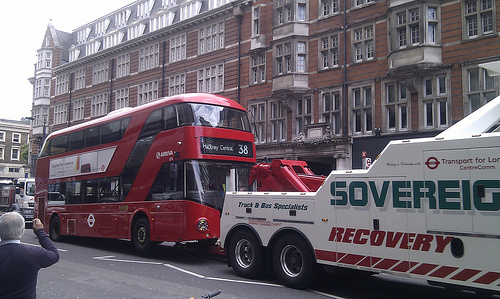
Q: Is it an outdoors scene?
A: Yes, it is outdoors.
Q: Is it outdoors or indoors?
A: It is outdoors.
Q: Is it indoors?
A: No, it is outdoors.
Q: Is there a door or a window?
A: Yes, there is a window.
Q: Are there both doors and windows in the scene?
A: No, there is a window but no doors.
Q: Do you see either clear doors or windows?
A: Yes, there is a clear window.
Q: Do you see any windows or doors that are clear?
A: Yes, the window is clear.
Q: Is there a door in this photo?
A: No, there are no doors.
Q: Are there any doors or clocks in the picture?
A: No, there are no doors or clocks.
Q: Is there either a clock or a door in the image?
A: No, there are no doors or clocks.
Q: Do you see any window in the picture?
A: Yes, there is a window.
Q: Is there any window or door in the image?
A: Yes, there is a window.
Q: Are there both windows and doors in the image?
A: No, there is a window but no doors.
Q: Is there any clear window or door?
A: Yes, there is a clear window.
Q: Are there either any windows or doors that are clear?
A: Yes, the window is clear.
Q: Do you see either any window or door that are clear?
A: Yes, the window is clear.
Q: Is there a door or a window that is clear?
A: Yes, the window is clear.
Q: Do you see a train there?
A: No, there are no trains.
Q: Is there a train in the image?
A: No, there are no trains.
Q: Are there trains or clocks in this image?
A: No, there are no trains or clocks.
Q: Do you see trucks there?
A: Yes, there is a truck.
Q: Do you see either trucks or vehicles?
A: Yes, there is a truck.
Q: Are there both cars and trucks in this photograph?
A: No, there is a truck but no cars.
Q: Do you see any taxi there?
A: No, there are no taxis.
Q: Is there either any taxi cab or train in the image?
A: No, there are no taxis or trains.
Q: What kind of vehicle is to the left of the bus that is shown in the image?
A: The vehicle is a truck.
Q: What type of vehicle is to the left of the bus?
A: The vehicle is a truck.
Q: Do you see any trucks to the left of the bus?
A: Yes, there is a truck to the left of the bus.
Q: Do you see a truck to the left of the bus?
A: Yes, there is a truck to the left of the bus.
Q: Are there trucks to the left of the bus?
A: Yes, there is a truck to the left of the bus.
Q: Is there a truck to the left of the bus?
A: Yes, there is a truck to the left of the bus.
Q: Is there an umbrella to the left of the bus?
A: No, there is a truck to the left of the bus.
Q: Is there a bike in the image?
A: No, there are no bikes.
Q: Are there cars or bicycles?
A: No, there are no bicycles or cars.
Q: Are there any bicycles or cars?
A: No, there are no bicycles or cars.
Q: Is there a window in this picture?
A: Yes, there are windows.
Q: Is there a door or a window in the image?
A: Yes, there are windows.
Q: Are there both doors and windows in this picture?
A: No, there are windows but no doors.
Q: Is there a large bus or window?
A: Yes, there are large windows.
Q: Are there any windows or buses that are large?
A: Yes, the windows are large.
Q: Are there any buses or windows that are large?
A: Yes, the windows are large.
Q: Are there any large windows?
A: Yes, there are large windows.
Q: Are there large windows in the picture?
A: Yes, there are large windows.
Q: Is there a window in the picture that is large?
A: Yes, there are windows that are large.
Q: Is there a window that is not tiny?
A: Yes, there are large windows.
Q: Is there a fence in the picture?
A: No, there are no fences.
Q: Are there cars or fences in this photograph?
A: No, there are no fences or cars.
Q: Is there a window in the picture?
A: Yes, there is a window.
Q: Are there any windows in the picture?
A: Yes, there is a window.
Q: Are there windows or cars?
A: Yes, there is a window.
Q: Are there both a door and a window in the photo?
A: No, there is a window but no doors.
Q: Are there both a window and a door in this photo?
A: No, there is a window but no doors.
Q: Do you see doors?
A: No, there are no doors.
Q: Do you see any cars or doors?
A: No, there are no doors or cars.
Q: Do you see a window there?
A: Yes, there is a window.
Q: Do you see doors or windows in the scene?
A: Yes, there is a window.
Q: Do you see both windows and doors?
A: No, there is a window but no doors.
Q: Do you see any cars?
A: No, there are no cars.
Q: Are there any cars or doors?
A: No, there are no cars or doors.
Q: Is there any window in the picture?
A: Yes, there is a window.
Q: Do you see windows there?
A: Yes, there is a window.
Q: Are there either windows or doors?
A: Yes, there is a window.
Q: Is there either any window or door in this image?
A: Yes, there is a window.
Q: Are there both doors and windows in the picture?
A: No, there is a window but no doors.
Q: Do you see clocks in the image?
A: No, there are no clocks.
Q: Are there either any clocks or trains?
A: No, there are no clocks or trains.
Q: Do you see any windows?
A: Yes, there is a window.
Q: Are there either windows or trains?
A: Yes, there is a window.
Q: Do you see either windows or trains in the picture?
A: Yes, there is a window.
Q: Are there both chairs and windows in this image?
A: No, there is a window but no chairs.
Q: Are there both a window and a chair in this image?
A: No, there is a window but no chairs.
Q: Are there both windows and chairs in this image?
A: No, there is a window but no chairs.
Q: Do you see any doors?
A: No, there are no doors.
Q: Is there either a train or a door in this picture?
A: No, there are no doors or trains.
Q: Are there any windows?
A: Yes, there is a window.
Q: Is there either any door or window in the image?
A: Yes, there is a window.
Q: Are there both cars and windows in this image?
A: No, there is a window but no cars.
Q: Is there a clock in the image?
A: No, there are no clocks.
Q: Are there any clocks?
A: No, there are no clocks.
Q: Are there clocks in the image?
A: No, there are no clocks.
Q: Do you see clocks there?
A: No, there are no clocks.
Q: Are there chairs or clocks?
A: No, there are no clocks or chairs.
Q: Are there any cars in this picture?
A: No, there are no cars.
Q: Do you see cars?
A: No, there are no cars.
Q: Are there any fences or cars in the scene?
A: No, there are no cars or fences.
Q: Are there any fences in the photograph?
A: No, there are no fences.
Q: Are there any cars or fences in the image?
A: No, there are no fences or cars.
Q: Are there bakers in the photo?
A: No, there are no bakers.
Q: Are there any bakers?
A: No, there are no bakers.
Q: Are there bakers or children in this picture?
A: No, there are no bakers or children.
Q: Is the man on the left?
A: Yes, the man is on the left of the image.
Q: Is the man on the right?
A: No, the man is on the left of the image.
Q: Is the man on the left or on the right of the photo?
A: The man is on the left of the image.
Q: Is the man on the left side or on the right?
A: The man is on the left of the image.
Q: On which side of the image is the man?
A: The man is on the left of the image.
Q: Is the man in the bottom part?
A: Yes, the man is in the bottom of the image.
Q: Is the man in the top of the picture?
A: No, the man is in the bottom of the image.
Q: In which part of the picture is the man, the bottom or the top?
A: The man is in the bottom of the image.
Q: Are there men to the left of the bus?
A: Yes, there is a man to the left of the bus.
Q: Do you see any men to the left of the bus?
A: Yes, there is a man to the left of the bus.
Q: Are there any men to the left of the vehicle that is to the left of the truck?
A: Yes, there is a man to the left of the bus.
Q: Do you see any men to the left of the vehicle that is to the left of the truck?
A: Yes, there is a man to the left of the bus.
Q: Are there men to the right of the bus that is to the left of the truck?
A: No, the man is to the left of the bus.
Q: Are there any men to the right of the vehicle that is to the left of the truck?
A: No, the man is to the left of the bus.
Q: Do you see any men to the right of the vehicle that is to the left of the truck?
A: No, the man is to the left of the bus.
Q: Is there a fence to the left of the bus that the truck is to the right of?
A: No, there is a man to the left of the bus.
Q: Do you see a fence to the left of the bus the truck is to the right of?
A: No, there is a man to the left of the bus.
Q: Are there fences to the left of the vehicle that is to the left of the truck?
A: No, there is a man to the left of the bus.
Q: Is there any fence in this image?
A: No, there are no fences.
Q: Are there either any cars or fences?
A: No, there are no fences or cars.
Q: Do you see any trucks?
A: Yes, there is a truck.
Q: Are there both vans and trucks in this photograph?
A: No, there is a truck but no vans.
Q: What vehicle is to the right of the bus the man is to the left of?
A: The vehicle is a truck.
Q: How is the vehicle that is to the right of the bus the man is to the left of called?
A: The vehicle is a truck.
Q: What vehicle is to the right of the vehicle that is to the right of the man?
A: The vehicle is a truck.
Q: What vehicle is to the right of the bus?
A: The vehicle is a truck.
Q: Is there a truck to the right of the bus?
A: Yes, there is a truck to the right of the bus.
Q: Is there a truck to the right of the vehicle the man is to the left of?
A: Yes, there is a truck to the right of the bus.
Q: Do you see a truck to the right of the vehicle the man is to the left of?
A: Yes, there is a truck to the right of the bus.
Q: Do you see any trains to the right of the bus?
A: No, there is a truck to the right of the bus.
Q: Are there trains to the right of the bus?
A: No, there is a truck to the right of the bus.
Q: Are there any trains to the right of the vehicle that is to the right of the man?
A: No, there is a truck to the right of the bus.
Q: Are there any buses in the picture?
A: Yes, there is a bus.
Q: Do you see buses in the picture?
A: Yes, there is a bus.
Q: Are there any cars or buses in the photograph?
A: Yes, there is a bus.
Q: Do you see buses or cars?
A: Yes, there is a bus.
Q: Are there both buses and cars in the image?
A: No, there is a bus but no cars.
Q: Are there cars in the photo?
A: No, there are no cars.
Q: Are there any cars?
A: No, there are no cars.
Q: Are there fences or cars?
A: No, there are no cars or fences.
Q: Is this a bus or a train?
A: This is a bus.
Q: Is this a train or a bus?
A: This is a bus.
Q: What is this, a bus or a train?
A: This is a bus.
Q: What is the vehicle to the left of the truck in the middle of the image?
A: The vehicle is a bus.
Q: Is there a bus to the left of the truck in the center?
A: Yes, there is a bus to the left of the truck.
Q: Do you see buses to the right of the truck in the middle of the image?
A: No, the bus is to the left of the truck.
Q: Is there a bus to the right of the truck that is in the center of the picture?
A: No, the bus is to the left of the truck.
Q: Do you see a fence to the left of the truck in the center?
A: No, there is a bus to the left of the truck.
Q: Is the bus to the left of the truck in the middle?
A: Yes, the bus is to the left of the truck.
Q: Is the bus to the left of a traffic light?
A: No, the bus is to the left of the truck.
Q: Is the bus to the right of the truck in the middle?
A: No, the bus is to the left of the truck.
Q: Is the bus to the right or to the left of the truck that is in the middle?
A: The bus is to the left of the truck.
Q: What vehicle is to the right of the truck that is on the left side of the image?
A: The vehicle is a bus.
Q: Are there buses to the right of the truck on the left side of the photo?
A: Yes, there is a bus to the right of the truck.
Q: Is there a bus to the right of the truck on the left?
A: Yes, there is a bus to the right of the truck.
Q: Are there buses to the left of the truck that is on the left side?
A: No, the bus is to the right of the truck.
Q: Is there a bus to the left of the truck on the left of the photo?
A: No, the bus is to the right of the truck.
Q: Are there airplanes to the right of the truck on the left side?
A: No, there is a bus to the right of the truck.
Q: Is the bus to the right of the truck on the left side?
A: Yes, the bus is to the right of the truck.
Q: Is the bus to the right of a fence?
A: No, the bus is to the right of the truck.